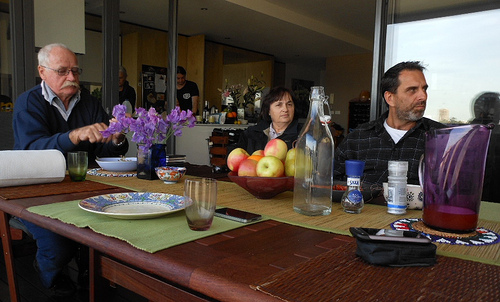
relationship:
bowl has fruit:
[228, 177, 292, 198] [230, 138, 295, 176]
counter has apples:
[78, 230, 347, 264] [230, 138, 295, 176]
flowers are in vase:
[109, 106, 194, 142] [138, 146, 165, 170]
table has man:
[84, 229, 346, 299] [8, 42, 131, 173]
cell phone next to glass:
[347, 225, 434, 241] [185, 180, 216, 230]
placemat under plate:
[97, 218, 189, 256] [106, 201, 173, 217]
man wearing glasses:
[13, 42, 110, 151] [55, 68, 85, 76]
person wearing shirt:
[13, 42, 110, 151] [48, 90, 59, 105]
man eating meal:
[8, 42, 131, 173] [103, 157, 135, 163]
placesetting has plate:
[42, 179, 218, 252] [106, 201, 173, 217]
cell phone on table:
[218, 205, 263, 225] [84, 229, 346, 299]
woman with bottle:
[252, 87, 300, 140] [293, 85, 334, 221]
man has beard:
[376, 62, 433, 157] [408, 111, 424, 118]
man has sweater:
[13, 42, 110, 151] [13, 100, 61, 152]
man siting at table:
[8, 42, 131, 173] [84, 229, 346, 299]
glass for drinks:
[185, 180, 216, 230] [419, 205, 477, 227]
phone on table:
[218, 205, 263, 225] [84, 229, 346, 299]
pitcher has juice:
[421, 120, 492, 235] [419, 205, 477, 227]